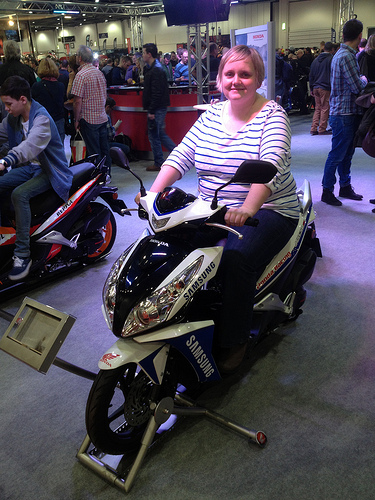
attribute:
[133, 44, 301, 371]
woman — smiling, blond, happy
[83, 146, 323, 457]
vehicle — modern, samsung, nice, new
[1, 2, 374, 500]
convention — large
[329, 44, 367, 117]
shirt — plaid, blue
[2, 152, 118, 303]
scooter — red, white, black, orange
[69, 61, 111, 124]
shirt — plaid, red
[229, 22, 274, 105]
sign — honda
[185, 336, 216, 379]
logo — white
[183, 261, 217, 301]
logo — black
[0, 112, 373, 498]
floor — sales, gray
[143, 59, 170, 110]
jacket — black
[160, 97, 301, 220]
shirt — striped, blue, white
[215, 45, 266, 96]
hair — short